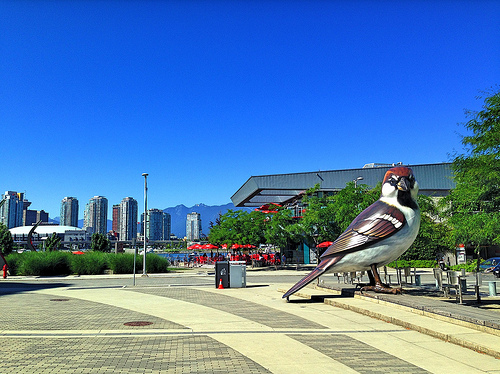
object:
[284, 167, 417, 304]
large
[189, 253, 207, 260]
table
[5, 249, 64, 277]
bushes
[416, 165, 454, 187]
grey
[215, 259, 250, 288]
two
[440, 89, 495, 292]
trees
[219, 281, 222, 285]
white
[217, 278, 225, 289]
cone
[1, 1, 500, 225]
clear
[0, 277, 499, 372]
cement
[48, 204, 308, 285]
view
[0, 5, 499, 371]
outdoor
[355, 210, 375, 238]
brown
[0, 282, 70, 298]
shadows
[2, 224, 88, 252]
stadium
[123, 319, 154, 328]
manhole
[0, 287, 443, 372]
ground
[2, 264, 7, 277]
red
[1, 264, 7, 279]
hydrant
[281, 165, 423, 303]
bird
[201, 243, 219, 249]
umbrellas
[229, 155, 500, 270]
building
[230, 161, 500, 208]
roof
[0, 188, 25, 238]
building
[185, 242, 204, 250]
umbrellas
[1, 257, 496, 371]
walkway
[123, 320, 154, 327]
grate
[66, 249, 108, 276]
shrubbery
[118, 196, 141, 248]
building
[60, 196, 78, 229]
building